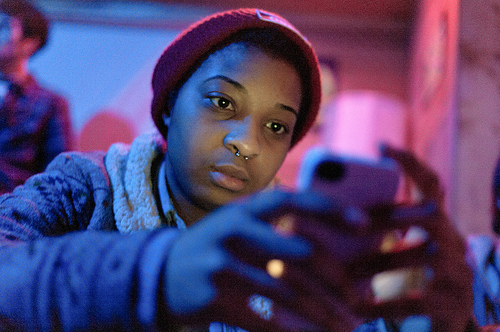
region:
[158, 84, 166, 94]
red fabric on hat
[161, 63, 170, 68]
red fabric on hat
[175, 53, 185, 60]
red fabric on hat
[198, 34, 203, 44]
red fabric on hat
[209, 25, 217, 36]
red fabric on hat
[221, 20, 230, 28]
red fabric on hat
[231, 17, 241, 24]
red fabric on hat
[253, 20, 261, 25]
red fabric on hat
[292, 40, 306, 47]
red fabric on hat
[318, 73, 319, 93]
red fabric on hat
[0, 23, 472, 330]
Girl wearing a sweater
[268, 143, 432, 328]
Phone in girl's hand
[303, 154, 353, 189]
Black lens on phone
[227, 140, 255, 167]
Ring in girl's nose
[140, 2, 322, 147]
Hat on the girl's head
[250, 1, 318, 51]
Label on the girl's hat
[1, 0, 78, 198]
Man standing in the background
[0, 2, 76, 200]
Man wearing a plaid shirt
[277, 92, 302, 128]
Eyebrow on girl's face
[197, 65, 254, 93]
Eyebrow on girl's face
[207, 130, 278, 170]
this person's nose is pierced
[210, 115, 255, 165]
they have a pierced septum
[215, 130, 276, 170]
their septum is pierced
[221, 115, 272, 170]
they have a pierced nose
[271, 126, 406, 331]
a cell phone in their hands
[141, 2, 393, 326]
they are staring at their phone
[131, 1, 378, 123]
a red cap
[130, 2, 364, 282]
they are wearing a red beanie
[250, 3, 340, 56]
there is a patch on their cap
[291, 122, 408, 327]
their phone case is white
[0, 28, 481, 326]
student with cell phone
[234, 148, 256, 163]
earring in kid's nose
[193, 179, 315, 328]
hand of the kid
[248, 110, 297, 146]
eye of the kid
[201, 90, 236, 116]
eye of the kid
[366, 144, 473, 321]
hand of the kid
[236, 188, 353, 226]
finger of the kid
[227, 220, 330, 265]
finger of the kid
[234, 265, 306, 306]
finger of the kid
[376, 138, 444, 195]
finger of the kid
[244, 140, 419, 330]
child holding a phone.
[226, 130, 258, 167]
child has a nose ring.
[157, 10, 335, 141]
child is wearing a hat.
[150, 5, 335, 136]
the hat is red.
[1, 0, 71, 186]
person in the background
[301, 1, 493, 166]
pink lights shining on everything.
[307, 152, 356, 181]
camera on the phone.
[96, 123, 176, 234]
th scarf is white.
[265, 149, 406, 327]
the phone is white.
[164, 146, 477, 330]
two hands on the phone.